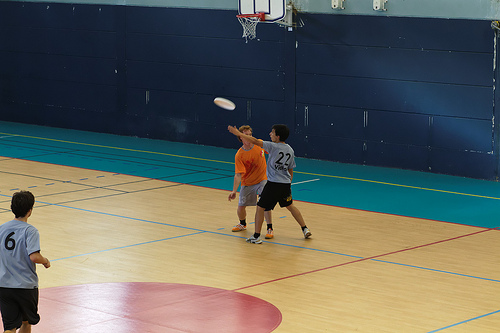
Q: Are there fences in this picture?
A: No, there are no fences.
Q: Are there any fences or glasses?
A: No, there are no fences or glasses.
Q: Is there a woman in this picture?
A: No, there are no women.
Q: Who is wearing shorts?
A: The boy is wearing shorts.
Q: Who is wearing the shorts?
A: The boy is wearing shorts.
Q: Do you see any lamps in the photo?
A: No, there are no lamps.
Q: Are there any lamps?
A: No, there are no lamps.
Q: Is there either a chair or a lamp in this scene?
A: No, there are no lamps or chairs.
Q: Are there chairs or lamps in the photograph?
A: No, there are no lamps or chairs.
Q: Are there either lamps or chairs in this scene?
A: No, there are no lamps or chairs.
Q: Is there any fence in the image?
A: No, there are no fences.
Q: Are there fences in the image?
A: No, there are no fences.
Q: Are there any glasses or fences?
A: No, there are no fences or glasses.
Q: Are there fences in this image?
A: No, there are no fences.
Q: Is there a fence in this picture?
A: No, there are no fences.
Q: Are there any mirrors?
A: No, there are no mirrors.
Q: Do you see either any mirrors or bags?
A: No, there are no mirrors or bags.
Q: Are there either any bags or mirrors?
A: No, there are no mirrors or bags.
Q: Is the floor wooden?
A: Yes, the floor is wooden.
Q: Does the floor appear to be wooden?
A: Yes, the floor is wooden.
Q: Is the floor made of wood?
A: Yes, the floor is made of wood.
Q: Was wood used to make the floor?
A: Yes, the floor is made of wood.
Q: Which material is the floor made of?
A: The floor is made of wood.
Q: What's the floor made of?
A: The floor is made of wood.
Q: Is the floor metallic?
A: No, the floor is wooden.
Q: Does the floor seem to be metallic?
A: No, the floor is wooden.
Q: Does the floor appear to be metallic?
A: No, the floor is wooden.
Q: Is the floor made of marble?
A: No, the floor is made of wood.